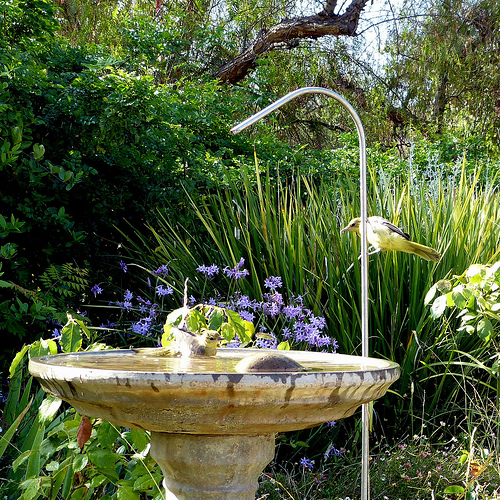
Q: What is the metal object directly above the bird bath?
A: A spigot.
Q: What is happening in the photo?
A: Bird is perched by a bird bath.